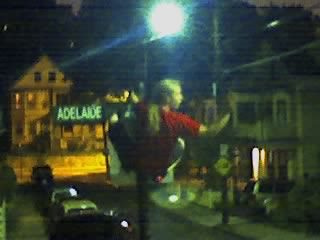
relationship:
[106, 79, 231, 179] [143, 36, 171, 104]
man hanging on a lamppost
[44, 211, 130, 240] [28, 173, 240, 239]
car along street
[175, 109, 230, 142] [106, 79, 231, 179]
arm of a man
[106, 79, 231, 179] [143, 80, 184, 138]
man with long hair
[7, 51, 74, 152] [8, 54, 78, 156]
facade of a building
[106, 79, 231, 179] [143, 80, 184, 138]
man with long blond hair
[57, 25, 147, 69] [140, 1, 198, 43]
glare from light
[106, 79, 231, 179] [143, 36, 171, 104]
man climbing lamppost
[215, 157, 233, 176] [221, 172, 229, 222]
sign on signpost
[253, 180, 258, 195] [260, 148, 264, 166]
glare from light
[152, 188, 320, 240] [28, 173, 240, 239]
sidewalk beside road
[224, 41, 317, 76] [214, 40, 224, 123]
line on pole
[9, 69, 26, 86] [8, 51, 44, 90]
part of roof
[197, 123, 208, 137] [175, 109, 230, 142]
part of an arm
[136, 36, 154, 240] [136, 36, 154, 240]
lamppost of a lamppost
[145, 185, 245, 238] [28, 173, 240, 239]
part of a street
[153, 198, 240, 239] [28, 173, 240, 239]
edge of a street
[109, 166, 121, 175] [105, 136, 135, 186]
part of a wall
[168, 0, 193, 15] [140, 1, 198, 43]
part of a light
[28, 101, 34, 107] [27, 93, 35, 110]
part of a window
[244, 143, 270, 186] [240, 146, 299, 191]
light on porch